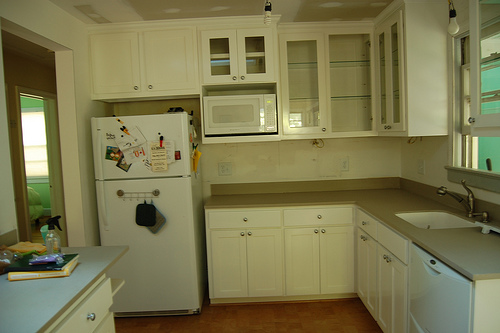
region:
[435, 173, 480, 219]
Silver faucet on white sink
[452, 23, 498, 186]
Window in front of sink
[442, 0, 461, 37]
Light bulb is dangling above sink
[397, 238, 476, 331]
White dishwasher near sink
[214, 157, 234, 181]
White electrical outlet next to white fridge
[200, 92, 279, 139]
White microwave next to white fridge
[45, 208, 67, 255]
Clear plastic bottle on top of counter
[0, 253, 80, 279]
Yellow and white book on counter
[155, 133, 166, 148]
Red magnet on fridge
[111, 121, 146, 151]
White paper on fridge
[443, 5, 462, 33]
Light bulb dangling above sink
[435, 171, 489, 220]
Silver faucet above sink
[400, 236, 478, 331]
White dishwasher next to sink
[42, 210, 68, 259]
Clear spray bottle on top of counter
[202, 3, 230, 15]
White paint spot on ceiling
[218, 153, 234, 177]
Electrical outlet next to white fridge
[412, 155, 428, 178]
Light switch near sink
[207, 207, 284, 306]
This is a kitchen drawer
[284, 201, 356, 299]
This is a kitchen drawer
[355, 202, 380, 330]
This is a kitchen drawer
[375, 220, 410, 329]
This is a kitchen drawer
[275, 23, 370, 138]
This is a kitchen drawer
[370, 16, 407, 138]
This is a kitchen drawer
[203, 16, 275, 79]
This is a kitchen drawer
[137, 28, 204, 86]
This is a kitchen drawer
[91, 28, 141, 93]
This is a kitchen drawer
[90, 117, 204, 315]
This is a fridge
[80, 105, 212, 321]
the small white fridge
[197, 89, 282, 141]
the small white microwave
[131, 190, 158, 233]
the black pot holder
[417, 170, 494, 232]
the metal sink faucet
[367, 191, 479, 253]
the small white sink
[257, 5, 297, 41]
the hanging energy saver light bulb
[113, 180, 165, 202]
the kitchen towel rack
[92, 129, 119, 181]
the handle on the freezer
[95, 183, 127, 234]
the handle on the fridge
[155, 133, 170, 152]
the red fridge magnet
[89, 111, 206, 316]
A white kitchen refridgerator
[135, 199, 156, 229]
A hanging hot pad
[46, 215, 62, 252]
A clear spray bottle with black nozzle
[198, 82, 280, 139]
A white microwave in a kitchen cubby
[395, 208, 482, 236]
An under the counter white kitchen sink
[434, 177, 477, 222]
A single knob faucet with detachable sprayer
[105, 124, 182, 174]
Photos and papers hung on a fridge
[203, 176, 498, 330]
A tan kitchen counter top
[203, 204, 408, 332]
White kitchen lower cabinets with silver knobs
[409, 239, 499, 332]
An under the counter dish washing machine